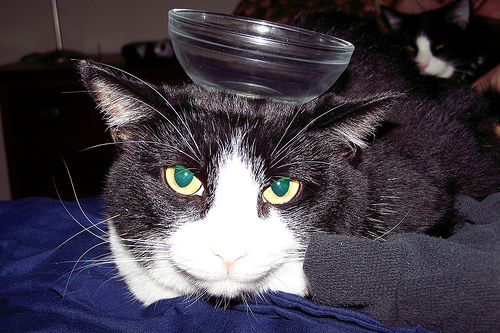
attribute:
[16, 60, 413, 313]
cat — piercing, black, looking, laying, white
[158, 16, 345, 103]
bowl — clear, glass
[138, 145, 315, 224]
eye — piercing, green, squinting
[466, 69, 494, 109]
hand — petting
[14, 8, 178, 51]
cabinet — brown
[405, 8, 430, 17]
sleeve — gray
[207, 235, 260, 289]
nose — pink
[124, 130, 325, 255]
face — white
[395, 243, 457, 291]
shirt — black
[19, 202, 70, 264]
blanket — blue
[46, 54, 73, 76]
table — wooden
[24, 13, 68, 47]
wall — grey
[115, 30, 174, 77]
lamp — silver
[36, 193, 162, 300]
whisker — white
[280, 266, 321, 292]
marking — white